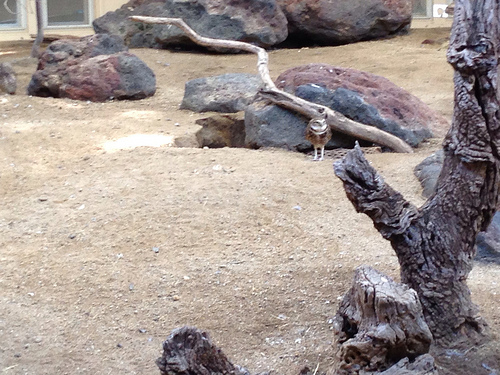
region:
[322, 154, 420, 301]
tree's texture is rough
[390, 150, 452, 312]
tree's texture is rough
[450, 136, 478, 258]
tree's texture is rough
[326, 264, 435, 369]
tree's texture is rough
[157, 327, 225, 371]
tree's texture is rough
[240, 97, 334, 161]
the rock is gray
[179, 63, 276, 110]
the rock is gray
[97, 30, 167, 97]
the rock is gray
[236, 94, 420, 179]
the rock is gray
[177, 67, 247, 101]
the rock is gray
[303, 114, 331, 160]
a owl on the ground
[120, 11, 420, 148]
a died tree limb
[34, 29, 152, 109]
a red and black rock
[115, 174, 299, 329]
dirt and rocks on the ground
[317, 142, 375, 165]
a woven netting on the ground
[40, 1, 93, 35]
a window on a building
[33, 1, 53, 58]
a gray tree trunk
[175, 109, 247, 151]
a hole by the rock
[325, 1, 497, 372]
a died treen with no leaves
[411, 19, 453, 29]
concrete tan wall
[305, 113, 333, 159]
small brown owl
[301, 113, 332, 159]
small owl with brown feathers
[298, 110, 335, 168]
small owl standing on the ground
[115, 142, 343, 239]
dirt on the ground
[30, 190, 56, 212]
small pebble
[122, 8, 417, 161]
long dried brown branch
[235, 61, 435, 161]
large rock behind owl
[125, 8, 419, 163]
large branch on a rock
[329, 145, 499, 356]
brown dead tree trunk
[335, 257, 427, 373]
tree stump in the dirt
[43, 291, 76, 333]
Small patch of dirt on ground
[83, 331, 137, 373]
Small patch of dirt on ground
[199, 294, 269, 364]
Small patch of dirt on ground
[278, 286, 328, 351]
Small patch of dirt on ground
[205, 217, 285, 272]
Small patch of dirt on ground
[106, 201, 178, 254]
Small patch of dirt on ground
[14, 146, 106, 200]
Small patch of dirt on ground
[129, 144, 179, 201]
Small patch of dirt on ground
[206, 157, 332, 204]
Small patch of dirt on ground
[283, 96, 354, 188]
Owl standing on the ground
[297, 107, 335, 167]
a brown small owl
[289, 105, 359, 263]
a brown small owl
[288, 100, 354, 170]
a brown small owl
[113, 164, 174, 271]
dirt on the ground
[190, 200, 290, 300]
dirt on the ground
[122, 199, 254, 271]
dirt on the ground